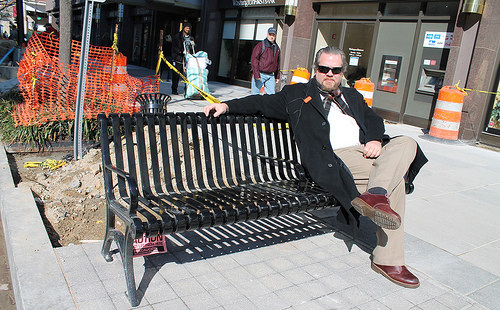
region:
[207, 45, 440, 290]
Man wearing a black coat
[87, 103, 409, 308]
Bench under the man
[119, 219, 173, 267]
Pink paper under bench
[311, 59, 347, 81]
Glasses on the man's face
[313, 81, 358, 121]
Scarf around the man's neck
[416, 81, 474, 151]
Safety cone next to building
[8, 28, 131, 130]
Orange net around a tree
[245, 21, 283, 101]
Man walking on sidewalk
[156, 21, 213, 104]
Man pushing a cart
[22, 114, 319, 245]
Pile of dirt behind bench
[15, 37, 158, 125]
Orange barricade fencing up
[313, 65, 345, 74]
Sunglasses being worn by a guy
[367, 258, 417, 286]
A red dress shoe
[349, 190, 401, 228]
A red casual dress shoe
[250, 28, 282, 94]
A man wearing a red jacket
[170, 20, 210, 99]
A man pushing some luggage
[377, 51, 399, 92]
An ATM vending machine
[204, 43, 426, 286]
A man sitting on a bench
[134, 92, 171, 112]
A black trash can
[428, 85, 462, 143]
An orange and white cone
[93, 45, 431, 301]
a man sitting on a bench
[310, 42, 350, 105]
a man wearing sunglasses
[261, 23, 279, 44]
a man wearing a blue cap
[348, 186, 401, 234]
the shoe of a man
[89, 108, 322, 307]
a black metal bench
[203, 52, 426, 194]
a man wearing a black coat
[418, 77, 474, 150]
a yellow and white construction barrel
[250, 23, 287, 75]
a man wearing a purple jacket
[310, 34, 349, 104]
a man with a beard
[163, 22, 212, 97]
a man pushing a cart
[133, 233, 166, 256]
pink paper with black writing on a park bench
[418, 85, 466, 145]
large orange and white safety cone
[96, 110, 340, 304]
black metal park bench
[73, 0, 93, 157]
metal silver sign pole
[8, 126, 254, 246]
dirt section in the pavement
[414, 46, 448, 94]
ATM machine in the wall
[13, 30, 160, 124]
orange plastic fencing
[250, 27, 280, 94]
man in black cap and red coat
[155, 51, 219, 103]
yellow caution tape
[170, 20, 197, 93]
man wearing all black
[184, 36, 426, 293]
dapper man sits on park bench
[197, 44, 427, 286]
man with cravat on park bench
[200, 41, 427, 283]
man with sunglasses on bench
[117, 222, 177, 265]
pink caution sign under bench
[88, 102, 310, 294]
black wrought metal bench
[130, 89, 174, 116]
black wrought metal trash can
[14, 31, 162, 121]
orange netting around tree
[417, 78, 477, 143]
orange and white warning barrels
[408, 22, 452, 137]
automated teller machine kiosk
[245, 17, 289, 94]
man in maroon windbreaker with backpack